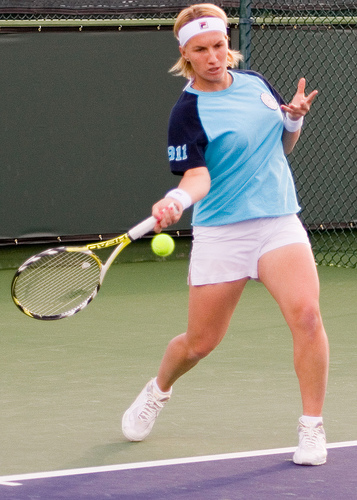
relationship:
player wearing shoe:
[119, 0, 331, 465] [116, 372, 177, 445]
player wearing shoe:
[119, 0, 331, 465] [290, 422, 327, 468]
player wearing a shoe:
[119, 0, 331, 465] [290, 411, 332, 472]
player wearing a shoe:
[119, 0, 331, 465] [122, 374, 175, 440]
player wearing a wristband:
[119, 0, 331, 465] [165, 187, 192, 208]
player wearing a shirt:
[119, 0, 331, 465] [161, 66, 310, 226]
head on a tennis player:
[172, 3, 235, 82] [154, 4, 317, 270]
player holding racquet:
[119, 0, 331, 465] [10, 202, 178, 319]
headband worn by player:
[175, 17, 226, 47] [119, 0, 331, 465]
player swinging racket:
[119, 0, 331, 465] [12, 197, 172, 311]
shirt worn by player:
[169, 67, 301, 224] [119, 0, 331, 465]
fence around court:
[244, 7, 350, 245] [0, 20, 355, 496]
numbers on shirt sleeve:
[164, 145, 188, 160] [162, 113, 209, 177]